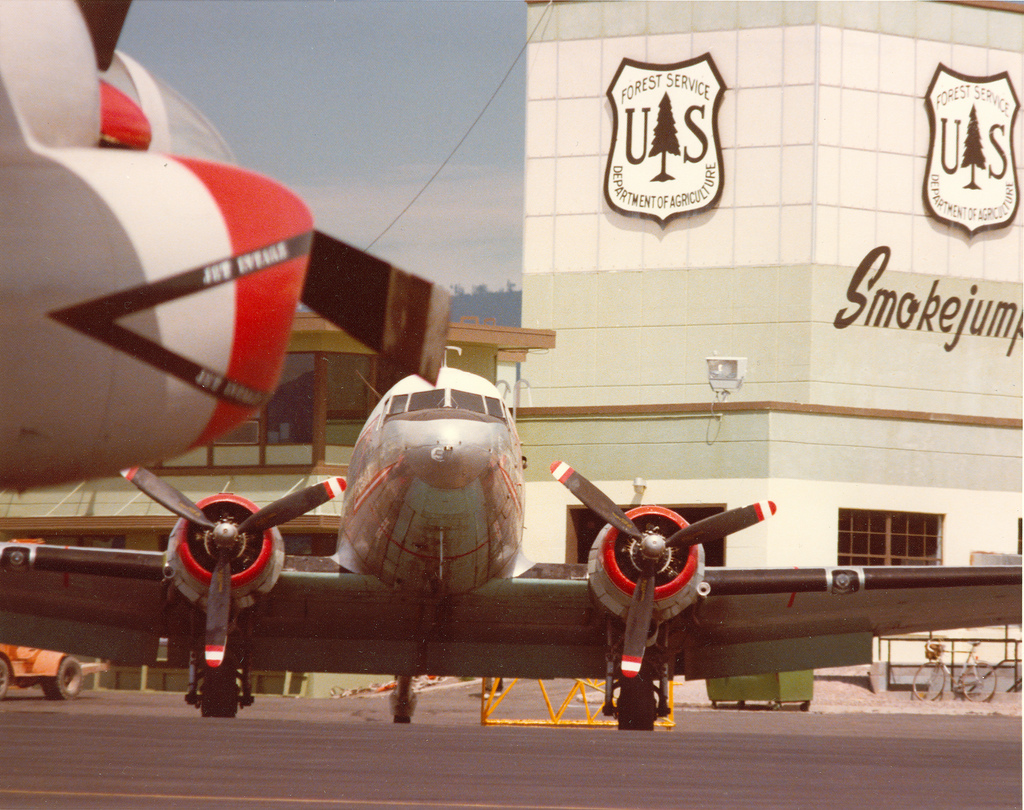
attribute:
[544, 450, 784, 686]
propellor — black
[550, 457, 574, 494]
tips — red, white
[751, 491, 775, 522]
tips — red, white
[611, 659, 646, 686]
tips — red, white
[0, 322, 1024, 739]
plane — parked, white, silver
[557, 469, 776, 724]
engine — red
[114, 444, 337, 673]
engine — red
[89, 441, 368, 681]
propeller — black, red, white, striped